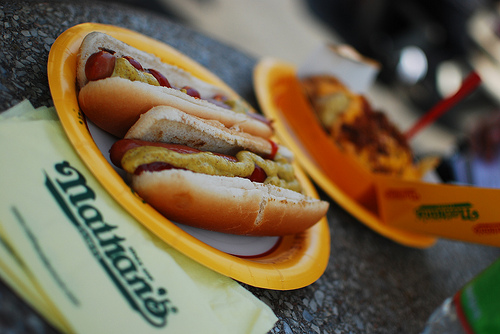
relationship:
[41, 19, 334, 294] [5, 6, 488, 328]
plate sitting on table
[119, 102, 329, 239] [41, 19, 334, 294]
bun sitting on plate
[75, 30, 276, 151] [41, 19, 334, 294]
bun sitting on plate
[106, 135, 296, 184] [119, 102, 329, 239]
frank sitting in bun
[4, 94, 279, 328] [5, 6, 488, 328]
napkin sitting on table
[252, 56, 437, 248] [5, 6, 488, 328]
plate sitting on table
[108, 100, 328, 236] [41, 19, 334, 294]
hot dog on plate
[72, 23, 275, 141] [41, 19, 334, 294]
hot dog on plate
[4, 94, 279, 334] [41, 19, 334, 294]
napkin next to plate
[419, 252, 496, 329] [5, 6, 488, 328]
bottle on table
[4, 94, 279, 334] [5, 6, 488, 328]
napkin on table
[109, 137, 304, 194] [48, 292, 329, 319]
hot dog on plate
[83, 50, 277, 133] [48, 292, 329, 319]
hot dog on plate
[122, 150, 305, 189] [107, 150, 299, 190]
mustard on hotdog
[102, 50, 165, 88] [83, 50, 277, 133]
mustard on hot dog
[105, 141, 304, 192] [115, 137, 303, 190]
ketchup on hotdog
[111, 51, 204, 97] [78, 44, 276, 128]
ketchup on hotdog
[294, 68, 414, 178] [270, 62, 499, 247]
food in box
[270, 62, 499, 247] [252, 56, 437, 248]
box on plate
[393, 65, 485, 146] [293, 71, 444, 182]
fork in food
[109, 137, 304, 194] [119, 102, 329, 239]
hot dog on bun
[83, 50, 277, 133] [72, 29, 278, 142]
hot dog on bun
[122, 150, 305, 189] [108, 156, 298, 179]
mustard on hot dog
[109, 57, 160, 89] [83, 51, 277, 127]
mustard on hot dog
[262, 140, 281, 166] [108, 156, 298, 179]
ketchup on hot dog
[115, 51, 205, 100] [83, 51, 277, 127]
ketchup on hot dog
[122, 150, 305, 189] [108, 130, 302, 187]
mustard on hot dog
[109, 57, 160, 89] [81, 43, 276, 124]
mustard on hot dog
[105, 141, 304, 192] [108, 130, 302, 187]
ketchup on hot dog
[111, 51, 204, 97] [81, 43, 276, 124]
ketchup on hot dog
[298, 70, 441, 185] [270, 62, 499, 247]
fries in box